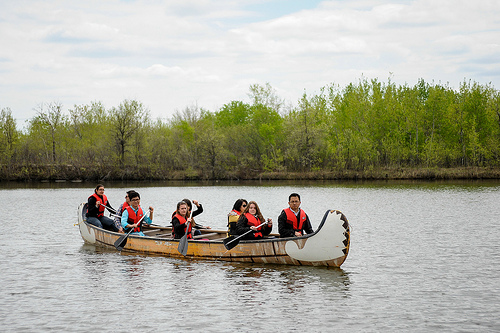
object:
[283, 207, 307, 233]
life jacket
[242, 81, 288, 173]
tree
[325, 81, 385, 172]
tree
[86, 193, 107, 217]
life vest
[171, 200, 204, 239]
people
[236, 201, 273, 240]
people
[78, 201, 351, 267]
boat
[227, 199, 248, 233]
person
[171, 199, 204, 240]
person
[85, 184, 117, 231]
man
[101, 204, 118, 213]
oar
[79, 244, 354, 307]
shadow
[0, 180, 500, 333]
water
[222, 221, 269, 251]
oar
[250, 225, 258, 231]
hand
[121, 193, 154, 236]
man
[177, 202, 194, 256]
oar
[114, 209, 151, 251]
oar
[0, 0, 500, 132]
sky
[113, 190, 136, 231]
man boat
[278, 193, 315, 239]
man